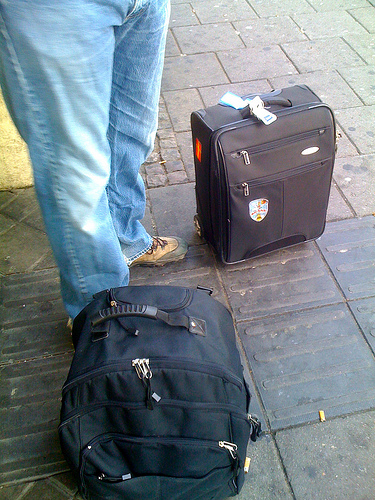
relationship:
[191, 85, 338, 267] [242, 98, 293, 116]
suitcase has handle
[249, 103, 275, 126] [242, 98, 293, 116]
tag on handle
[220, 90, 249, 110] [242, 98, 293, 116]
tag on handle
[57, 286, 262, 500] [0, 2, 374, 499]
bag sitting on ground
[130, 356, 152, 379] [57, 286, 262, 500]
zipper on bag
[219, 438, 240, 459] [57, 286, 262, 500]
zipper on bag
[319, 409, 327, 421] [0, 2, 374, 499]
cigarette butt on ground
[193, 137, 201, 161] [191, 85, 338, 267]
patch on suitcase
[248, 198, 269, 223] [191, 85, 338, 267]
patch on suitcase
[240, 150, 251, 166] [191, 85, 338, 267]
zipper on suitcase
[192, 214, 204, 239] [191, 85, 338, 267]
wheel on suitcase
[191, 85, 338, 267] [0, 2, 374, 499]
suitcase on ground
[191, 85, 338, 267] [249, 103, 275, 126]
suitcase has tag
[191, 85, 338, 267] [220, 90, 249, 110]
suitcase has tag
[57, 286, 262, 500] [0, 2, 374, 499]
bag on ground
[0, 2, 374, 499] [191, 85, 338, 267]
ground under suitcase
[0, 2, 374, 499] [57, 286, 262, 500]
ground under bag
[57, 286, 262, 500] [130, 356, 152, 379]
bag has zipper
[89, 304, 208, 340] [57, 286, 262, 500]
handle on top of bag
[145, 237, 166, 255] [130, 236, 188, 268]
lace on shoe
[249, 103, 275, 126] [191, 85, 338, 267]
tag on suitcase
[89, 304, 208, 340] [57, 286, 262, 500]
handle on bag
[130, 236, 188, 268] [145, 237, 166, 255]
shoe has lace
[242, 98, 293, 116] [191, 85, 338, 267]
handle on suitcase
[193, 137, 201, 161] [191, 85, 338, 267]
patch on side of suitcase